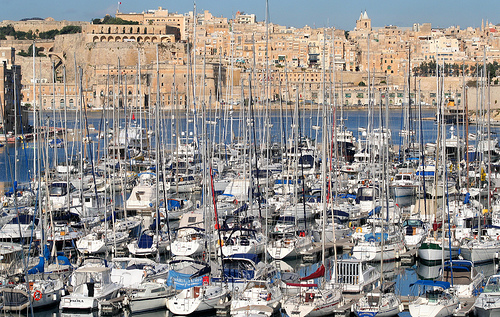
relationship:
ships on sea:
[123, 190, 248, 251] [206, 123, 234, 135]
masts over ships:
[188, 276, 206, 284] [123, 190, 248, 251]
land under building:
[46, 102, 65, 109] [85, 14, 161, 54]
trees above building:
[101, 12, 132, 22] [85, 14, 161, 54]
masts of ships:
[188, 276, 206, 284] [123, 190, 248, 251]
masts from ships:
[188, 276, 206, 284] [123, 190, 248, 251]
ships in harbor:
[123, 190, 248, 251] [236, 120, 284, 142]